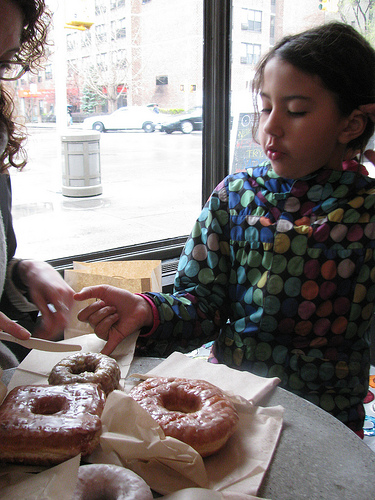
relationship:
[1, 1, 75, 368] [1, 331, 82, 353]
adult holds knife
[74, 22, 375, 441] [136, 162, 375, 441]
girl wearing blouse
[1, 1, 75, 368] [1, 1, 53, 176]
adult has hair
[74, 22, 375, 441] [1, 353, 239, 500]
girl in front of donuts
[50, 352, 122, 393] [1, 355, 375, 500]
donut on table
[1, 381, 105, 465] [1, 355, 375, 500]
donut on table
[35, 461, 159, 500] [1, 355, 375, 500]
donuts on table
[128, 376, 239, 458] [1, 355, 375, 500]
donut on table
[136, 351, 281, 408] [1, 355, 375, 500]
napkin on table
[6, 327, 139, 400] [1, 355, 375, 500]
napkin on table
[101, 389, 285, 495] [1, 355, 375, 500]
napkin on table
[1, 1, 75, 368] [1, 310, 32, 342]
adult has hand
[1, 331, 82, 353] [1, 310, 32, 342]
knife in hand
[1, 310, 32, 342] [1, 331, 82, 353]
hand on knife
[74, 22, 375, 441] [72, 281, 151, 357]
girl has hand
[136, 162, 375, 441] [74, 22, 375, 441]
blouse on girl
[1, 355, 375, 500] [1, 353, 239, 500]
table under donuts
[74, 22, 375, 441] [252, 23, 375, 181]
girl has head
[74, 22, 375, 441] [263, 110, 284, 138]
girl has nose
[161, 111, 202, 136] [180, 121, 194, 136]
car has tire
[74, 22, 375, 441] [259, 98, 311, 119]
girl has eyes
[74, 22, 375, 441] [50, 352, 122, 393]
girl touching donut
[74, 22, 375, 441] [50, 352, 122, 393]
girl looking at donut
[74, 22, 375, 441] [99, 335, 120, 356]
girl has finger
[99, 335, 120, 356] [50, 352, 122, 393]
finger touching donut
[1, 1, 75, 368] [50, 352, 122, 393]
adult cutting donut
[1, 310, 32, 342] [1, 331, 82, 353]
hand touching knife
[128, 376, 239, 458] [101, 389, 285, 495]
donut on napkin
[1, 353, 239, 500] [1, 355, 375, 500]
donuts are on table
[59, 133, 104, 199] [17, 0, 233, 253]
trash can behind window